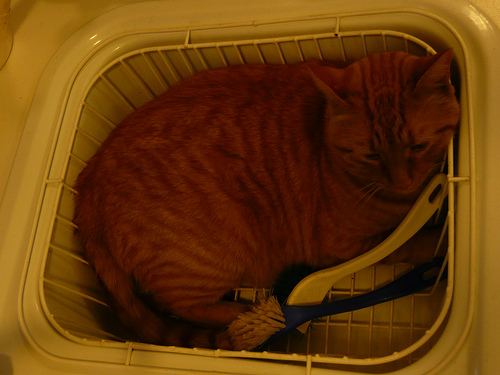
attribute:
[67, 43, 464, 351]
cat — lying down, looking forward, striped, orange, brown, curled up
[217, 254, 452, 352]
scrub brush — blue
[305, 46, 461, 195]
head — striped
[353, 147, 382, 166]
eye — dark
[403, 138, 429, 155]
eye — dark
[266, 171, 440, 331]
scrub brush — white, black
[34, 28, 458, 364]
wire basket — metal, white, rectangular, coated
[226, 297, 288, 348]
bristles — white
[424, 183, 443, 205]
opening — oval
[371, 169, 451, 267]
handle — white, black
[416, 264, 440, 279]
opening — oval